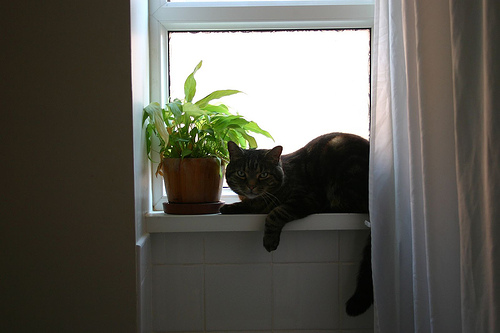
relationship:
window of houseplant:
[161, 24, 370, 210] [142, 61, 272, 217]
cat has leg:
[216, 131, 401, 320] [263, 200, 309, 253]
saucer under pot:
[161, 200, 225, 215] [159, 154, 224, 202]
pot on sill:
[149, 145, 234, 210] [145, 199, 365, 231]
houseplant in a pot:
[139, 70, 249, 223] [154, 140, 235, 223]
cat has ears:
[216, 131, 371, 253] [223, 137, 285, 160]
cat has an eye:
[216, 131, 401, 320] [264, 170, 274, 181]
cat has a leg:
[216, 131, 371, 253] [213, 200, 263, 215]